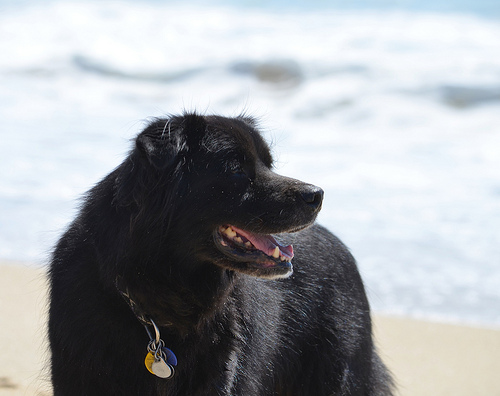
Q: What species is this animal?
A: Dog.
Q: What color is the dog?
A: Black.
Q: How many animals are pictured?
A: One.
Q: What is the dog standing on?
A: Sand.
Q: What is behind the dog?
A: The ocean.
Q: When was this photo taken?
A: Day time.